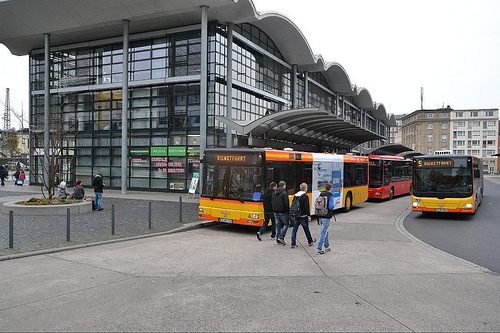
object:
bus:
[410, 153, 485, 215]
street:
[2, 180, 496, 331]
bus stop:
[0, 153, 430, 333]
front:
[197, 147, 267, 227]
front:
[411, 154, 475, 214]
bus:
[196, 147, 372, 230]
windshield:
[202, 157, 264, 202]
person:
[314, 182, 337, 254]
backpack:
[314, 195, 328, 217]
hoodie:
[316, 190, 336, 218]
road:
[174, 228, 247, 300]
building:
[28, 29, 219, 191]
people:
[73, 180, 86, 200]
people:
[256, 181, 335, 256]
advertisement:
[148, 146, 190, 190]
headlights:
[198, 206, 261, 221]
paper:
[313, 155, 343, 211]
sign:
[188, 172, 200, 194]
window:
[267, 164, 297, 188]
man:
[289, 182, 317, 249]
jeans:
[290, 215, 314, 246]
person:
[270, 180, 292, 245]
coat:
[272, 194, 289, 215]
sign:
[134, 157, 185, 174]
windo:
[132, 107, 200, 146]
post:
[108, 200, 116, 236]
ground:
[85, 217, 112, 240]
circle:
[2, 195, 93, 209]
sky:
[383, 13, 444, 70]